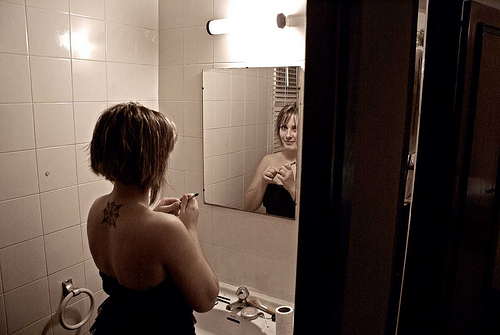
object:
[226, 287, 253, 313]
faucet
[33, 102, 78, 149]
tile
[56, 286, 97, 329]
hanger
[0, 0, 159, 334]
wall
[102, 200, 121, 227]
tattoo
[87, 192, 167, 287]
back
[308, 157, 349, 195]
ground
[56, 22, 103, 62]
reflection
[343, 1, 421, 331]
jamb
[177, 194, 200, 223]
hands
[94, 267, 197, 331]
dress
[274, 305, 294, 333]
roll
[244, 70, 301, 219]
reflection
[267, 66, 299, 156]
window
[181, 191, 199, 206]
something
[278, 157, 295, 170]
something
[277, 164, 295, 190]
hands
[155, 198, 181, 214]
hands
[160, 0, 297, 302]
wall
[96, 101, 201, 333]
lady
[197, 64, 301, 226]
mirror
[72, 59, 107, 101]
tiles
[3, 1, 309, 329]
bathroom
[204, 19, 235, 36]
light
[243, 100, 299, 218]
herself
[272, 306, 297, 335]
tissue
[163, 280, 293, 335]
sink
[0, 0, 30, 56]
tile